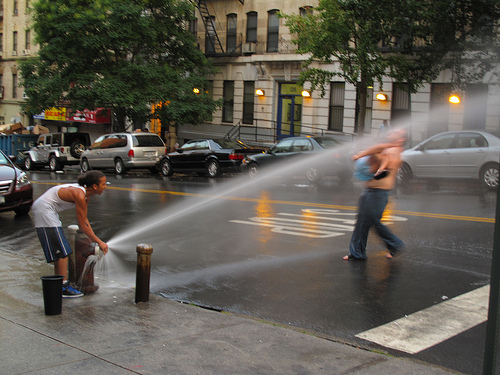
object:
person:
[340, 128, 408, 262]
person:
[28, 170, 105, 298]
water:
[78, 90, 499, 294]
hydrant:
[73, 228, 102, 293]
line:
[354, 284, 491, 354]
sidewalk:
[0, 271, 469, 374]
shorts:
[36, 227, 73, 264]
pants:
[348, 188, 406, 258]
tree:
[17, 0, 225, 132]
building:
[0, 0, 499, 152]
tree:
[276, 0, 499, 151]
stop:
[227, 208, 408, 238]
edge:
[354, 332, 417, 355]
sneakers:
[61, 282, 86, 298]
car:
[80, 132, 168, 175]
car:
[24, 132, 92, 173]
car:
[158, 136, 265, 177]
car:
[240, 134, 354, 184]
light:
[254, 88, 264, 96]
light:
[300, 89, 312, 98]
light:
[375, 93, 387, 101]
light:
[447, 94, 459, 104]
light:
[193, 87, 201, 93]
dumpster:
[0, 121, 52, 164]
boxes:
[0, 121, 23, 135]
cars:
[0, 149, 35, 217]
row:
[0, 163, 499, 374]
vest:
[28, 181, 86, 227]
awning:
[250, 54, 312, 81]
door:
[277, 81, 304, 138]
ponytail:
[77, 175, 85, 186]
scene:
[0, 0, 499, 374]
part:
[348, 227, 368, 260]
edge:
[35, 222, 62, 227]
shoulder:
[74, 188, 86, 202]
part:
[79, 193, 84, 199]